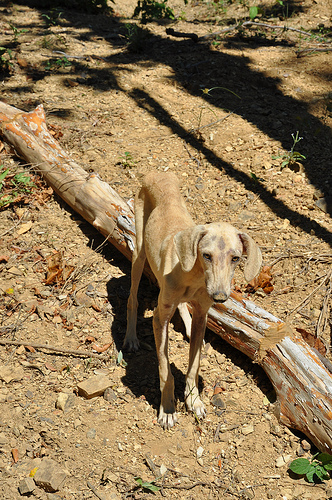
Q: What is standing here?
A: Dog.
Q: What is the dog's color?
A: Brown.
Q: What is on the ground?
A: A log.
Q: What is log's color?
A: Tan.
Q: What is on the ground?
A: Leaves.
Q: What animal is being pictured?
A: Dog.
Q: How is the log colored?
A: Brown.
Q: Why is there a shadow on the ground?
A: It is very sunny outside.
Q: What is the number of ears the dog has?
A: Two.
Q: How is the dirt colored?
A: Brown.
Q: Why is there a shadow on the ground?
A: The sun is very sunny.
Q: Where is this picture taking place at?
A: Forest.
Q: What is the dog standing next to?
A: A branch.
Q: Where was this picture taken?
A: In the woods.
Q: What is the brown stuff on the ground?
A: Dirt.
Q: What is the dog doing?
A: Standing.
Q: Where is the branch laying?
A: On the ground.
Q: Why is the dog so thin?
A: It is starved.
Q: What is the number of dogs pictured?
A: One.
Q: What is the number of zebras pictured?
A: Zero.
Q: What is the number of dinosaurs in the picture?
A: Zero.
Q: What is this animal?
A: A dog.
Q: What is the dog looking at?
A: At the photographer.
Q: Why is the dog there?
A: Because it's feral.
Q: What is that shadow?
A: A shadow from a tree.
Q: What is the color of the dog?
A: A palish brown.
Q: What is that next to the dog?
A: A broken tree branch.